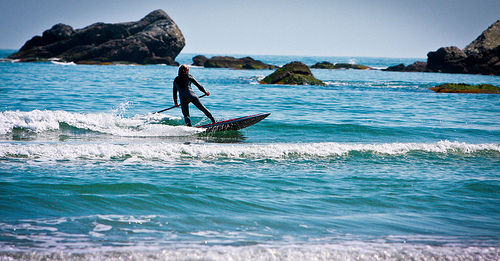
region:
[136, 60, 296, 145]
The person is surfing.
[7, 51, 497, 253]
The ocean is greenish-blue.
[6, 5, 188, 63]
The rock is big.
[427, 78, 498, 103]
The island is grassy.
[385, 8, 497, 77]
The island is rocky.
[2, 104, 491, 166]
The waves are foaming.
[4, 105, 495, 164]
The waves are white.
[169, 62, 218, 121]
The person is wearing blue.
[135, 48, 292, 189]
The person is in the water.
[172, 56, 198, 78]
The hair is blonde.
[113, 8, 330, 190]
the woman paddles the kayak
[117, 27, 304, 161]
the woman holds the paddle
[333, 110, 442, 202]
the water is blue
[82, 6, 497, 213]
the rocks are sharp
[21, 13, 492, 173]
a rocky shore to navigate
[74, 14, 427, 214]
the rocks are black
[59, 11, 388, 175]
the woman is standing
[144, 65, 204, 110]
her wetsuit is black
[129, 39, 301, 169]
she is wearing a wetsuit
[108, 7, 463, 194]
the woman is alone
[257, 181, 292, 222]
part of a water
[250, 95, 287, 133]
tip of a board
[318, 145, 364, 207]
part of a water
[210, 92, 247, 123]
edge of a board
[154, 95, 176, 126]
part of a stick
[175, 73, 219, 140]
part of a codtume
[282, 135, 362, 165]
Small white breaking waves.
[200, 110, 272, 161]
Surfboard floating on water.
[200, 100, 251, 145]
Red and navy surfboard.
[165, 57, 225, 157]
Women surfing in small waves.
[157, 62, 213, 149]
Woman holding paddle.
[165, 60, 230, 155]
Dark colored wetsuit on woman.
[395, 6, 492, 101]
Large rocks in the water.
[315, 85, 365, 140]
Bright blue wavy water.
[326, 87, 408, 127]
Small ripples in the water.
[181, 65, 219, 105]
Right arm holding paddle.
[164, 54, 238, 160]
Paddle in hands.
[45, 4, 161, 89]
Large rock jutting from water.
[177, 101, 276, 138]
Surf board on water surface.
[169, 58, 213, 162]
Woman surfing on water.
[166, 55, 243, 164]
Dark colored wet suit.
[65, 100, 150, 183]
Small breaking waves on water.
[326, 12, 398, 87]
Gray sky in background.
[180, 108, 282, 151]
Red and navy surfboard on water.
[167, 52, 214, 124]
Long blond hair on woman.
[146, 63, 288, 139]
the girl is surfing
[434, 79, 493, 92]
A rock in the water.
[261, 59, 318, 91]
A rock in the water.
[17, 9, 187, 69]
A rock in the water.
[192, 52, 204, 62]
A rock in the water.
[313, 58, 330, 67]
A rock in the water.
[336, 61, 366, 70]
A rock in the water.